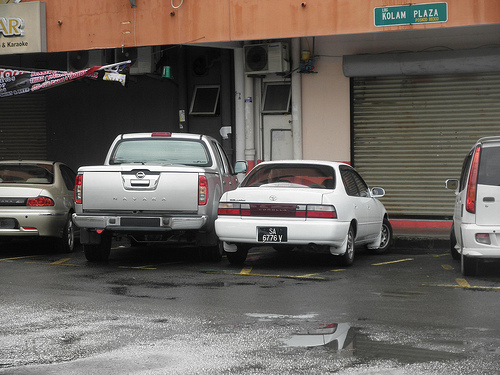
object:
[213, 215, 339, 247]
back bumper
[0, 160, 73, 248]
sedan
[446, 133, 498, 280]
suv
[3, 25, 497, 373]
parking lot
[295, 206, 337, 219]
light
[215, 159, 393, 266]
car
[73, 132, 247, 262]
truck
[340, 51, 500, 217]
door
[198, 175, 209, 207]
light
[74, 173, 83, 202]
light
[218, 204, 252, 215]
tail light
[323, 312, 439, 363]
puddle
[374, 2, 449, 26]
sign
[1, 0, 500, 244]
building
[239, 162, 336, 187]
windshield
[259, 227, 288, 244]
license plates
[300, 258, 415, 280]
lines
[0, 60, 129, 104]
banner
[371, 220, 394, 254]
tire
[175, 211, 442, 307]
spot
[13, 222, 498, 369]
pavement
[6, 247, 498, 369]
lot